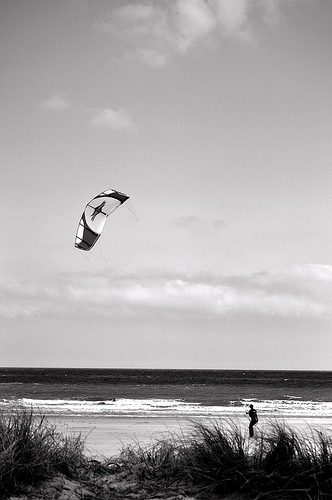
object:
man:
[246, 404, 259, 437]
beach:
[3, 353, 331, 487]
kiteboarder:
[74, 188, 131, 252]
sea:
[0, 367, 331, 429]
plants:
[4, 431, 331, 499]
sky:
[9, 1, 327, 228]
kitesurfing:
[74, 188, 259, 439]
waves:
[7, 396, 331, 414]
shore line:
[9, 409, 331, 431]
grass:
[4, 410, 331, 498]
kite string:
[219, 392, 251, 415]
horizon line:
[2, 354, 331, 381]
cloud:
[150, 3, 227, 50]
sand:
[41, 413, 331, 448]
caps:
[249, 403, 253, 409]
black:
[246, 409, 258, 437]